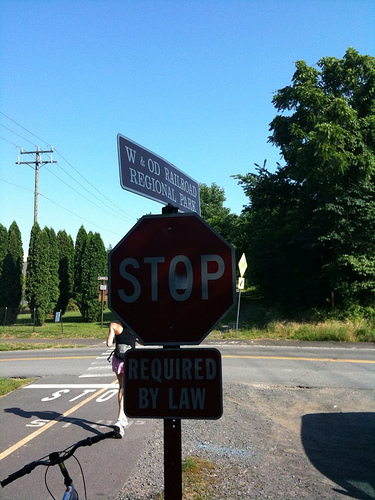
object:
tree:
[24, 219, 50, 325]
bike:
[0, 429, 118, 498]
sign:
[108, 217, 235, 341]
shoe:
[114, 424, 125, 444]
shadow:
[5, 407, 117, 440]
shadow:
[301, 415, 373, 497]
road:
[0, 335, 373, 497]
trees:
[289, 44, 375, 317]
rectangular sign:
[116, 136, 202, 217]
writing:
[134, 389, 147, 414]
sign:
[118, 343, 224, 424]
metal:
[192, 225, 219, 246]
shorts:
[110, 353, 123, 373]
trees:
[0, 227, 19, 323]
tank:
[112, 320, 136, 347]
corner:
[0, 310, 105, 344]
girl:
[107, 315, 129, 438]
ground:
[31, 351, 361, 495]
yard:
[0, 295, 340, 343]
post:
[162, 413, 184, 496]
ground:
[0, 348, 362, 497]